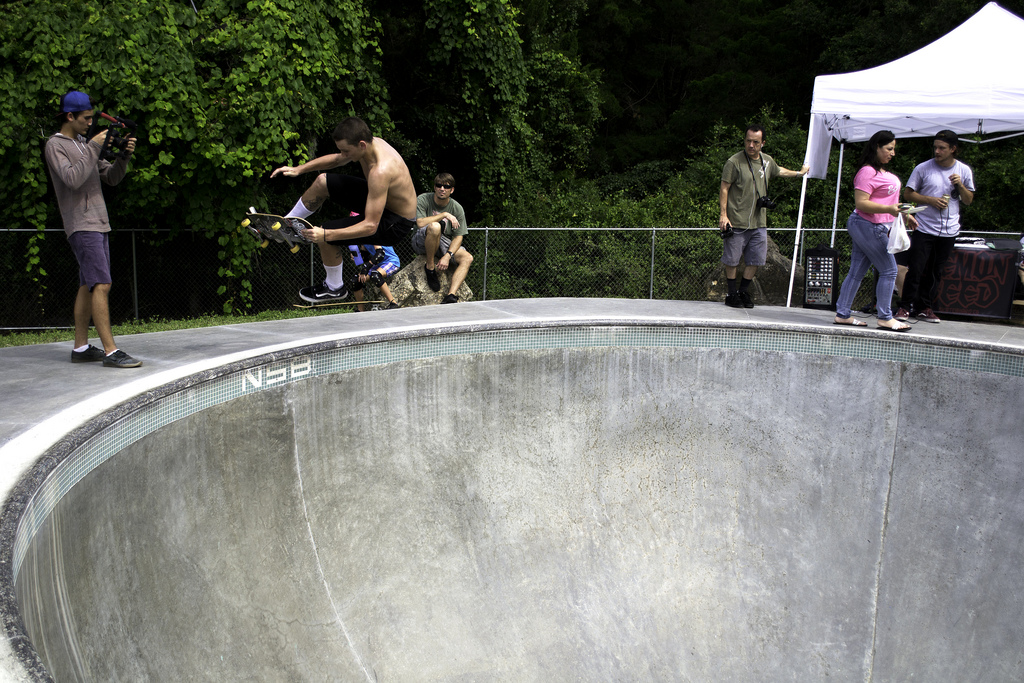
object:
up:
[718, 126, 920, 331]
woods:
[0, 1, 1024, 296]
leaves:
[135, 87, 214, 172]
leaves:
[221, 35, 304, 74]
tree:
[0, 0, 392, 314]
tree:
[113, 5, 367, 198]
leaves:
[194, 59, 309, 133]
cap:
[58, 91, 93, 118]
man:
[43, 92, 142, 367]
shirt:
[46, 133, 114, 238]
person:
[718, 126, 809, 308]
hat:
[58, 91, 93, 112]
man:
[717, 123, 810, 309]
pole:
[786, 76, 844, 308]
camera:
[99, 112, 156, 162]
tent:
[718, 120, 976, 332]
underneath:
[833, 209, 912, 332]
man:
[241, 117, 419, 302]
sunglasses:
[435, 184, 454, 190]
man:
[411, 173, 474, 305]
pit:
[0, 320, 1024, 683]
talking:
[833, 130, 972, 332]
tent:
[788, 203, 810, 232]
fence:
[169, 226, 238, 335]